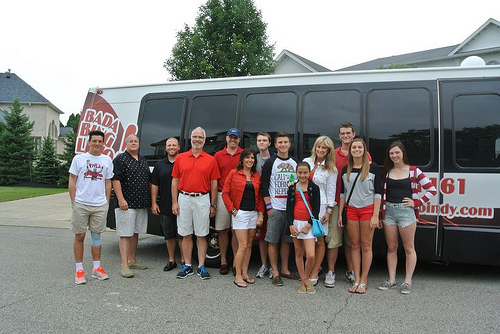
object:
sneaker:
[177, 264, 194, 279]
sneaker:
[196, 264, 211, 280]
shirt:
[172, 149, 221, 194]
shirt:
[214, 146, 245, 191]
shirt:
[339, 161, 383, 209]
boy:
[67, 130, 115, 286]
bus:
[72, 64, 500, 269]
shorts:
[69, 203, 110, 233]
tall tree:
[165, 0, 282, 79]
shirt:
[68, 152, 114, 207]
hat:
[227, 127, 241, 138]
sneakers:
[73, 267, 87, 285]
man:
[171, 126, 221, 280]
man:
[262, 130, 298, 288]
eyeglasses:
[192, 136, 204, 139]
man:
[112, 132, 149, 279]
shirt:
[110, 151, 150, 210]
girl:
[284, 162, 321, 295]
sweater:
[287, 179, 320, 226]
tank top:
[380, 167, 418, 202]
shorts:
[231, 209, 260, 230]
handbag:
[297, 182, 326, 238]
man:
[151, 137, 180, 272]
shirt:
[148, 156, 176, 215]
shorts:
[174, 189, 211, 236]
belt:
[179, 190, 208, 197]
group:
[68, 121, 437, 295]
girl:
[377, 139, 436, 294]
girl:
[222, 146, 265, 289]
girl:
[337, 136, 385, 293]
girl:
[303, 135, 339, 287]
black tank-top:
[386, 169, 412, 203]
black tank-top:
[239, 180, 256, 211]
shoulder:
[287, 182, 299, 195]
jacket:
[286, 179, 320, 226]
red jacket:
[221, 169, 264, 214]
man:
[325, 122, 373, 287]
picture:
[1, 0, 500, 332]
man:
[217, 125, 247, 274]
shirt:
[334, 146, 372, 206]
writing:
[421, 178, 495, 221]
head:
[225, 128, 243, 151]